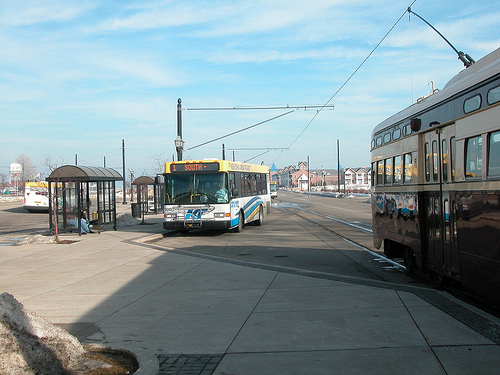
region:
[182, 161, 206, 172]
The word south on a bus.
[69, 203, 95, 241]
A person sitting in a bus stop.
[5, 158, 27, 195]
A water tower.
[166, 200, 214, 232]
A bicycle rack on a bus.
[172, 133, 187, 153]
A pair of street lights just above a bus.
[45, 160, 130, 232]
A bus stop sitting area.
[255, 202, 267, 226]
The rear tire of a bus.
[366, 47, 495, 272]
An electric car or trolley.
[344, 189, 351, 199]
A red fire hydrant.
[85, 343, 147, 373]
An area of grass visible next to snow.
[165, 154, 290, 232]
bold bus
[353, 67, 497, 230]
old light rail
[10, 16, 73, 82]
white clouds in blue sky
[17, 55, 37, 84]
white clouds in blue sky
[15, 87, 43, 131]
white clouds in blue sky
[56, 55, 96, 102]
white clouds in blue sky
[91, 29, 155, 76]
white clouds in blue sky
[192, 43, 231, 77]
white clouds in blue sky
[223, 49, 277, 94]
white clouds in blue sky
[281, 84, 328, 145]
white clouds in blue sky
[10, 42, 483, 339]
a bus driving on the road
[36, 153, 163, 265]
bus shelters in the area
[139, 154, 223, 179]
a bus route sign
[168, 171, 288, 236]
this bus is white with blue trim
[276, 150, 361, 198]
housing in the background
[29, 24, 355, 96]
blue skies above the area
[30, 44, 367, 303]
the sun is shining down from above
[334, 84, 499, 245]
a cable car in the city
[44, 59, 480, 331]
a scene with public transportation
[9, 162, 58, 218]
a bus in the background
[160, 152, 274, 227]
passenger bus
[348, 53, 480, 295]
old light rail car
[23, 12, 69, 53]
white clouds in blue sky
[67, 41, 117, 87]
white clouds in blue sky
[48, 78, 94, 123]
white clouds in blue sky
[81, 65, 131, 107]
white clouds in blue sky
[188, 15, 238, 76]
white clouds in blue sky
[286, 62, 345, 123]
white clouds in blue sky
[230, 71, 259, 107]
white clouds in blue sky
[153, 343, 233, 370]
small grate on the ground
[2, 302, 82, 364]
mound of brown snow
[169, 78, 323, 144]
electrical wires in the air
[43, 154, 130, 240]
large black bus stop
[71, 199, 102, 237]
person sitting in seat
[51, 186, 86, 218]
clear cover at side of bus stop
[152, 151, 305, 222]
passenger bus at stop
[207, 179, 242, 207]
bus driver in seat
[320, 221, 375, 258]
small amount of snow on street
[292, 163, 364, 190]
large apartments in the rear